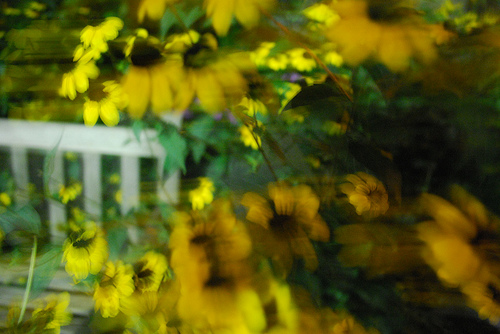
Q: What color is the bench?
A: White.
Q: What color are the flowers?
A: Yellow.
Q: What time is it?
A: Daytime.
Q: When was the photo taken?
A: Afternoon.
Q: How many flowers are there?
A: More than five.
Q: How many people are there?
A: None.